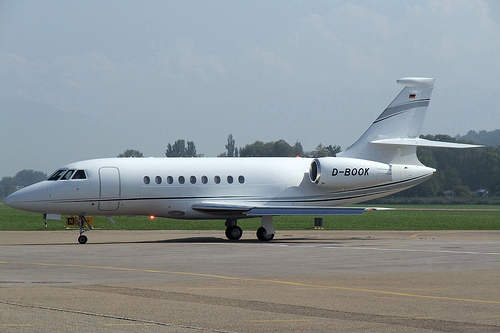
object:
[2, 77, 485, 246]
plane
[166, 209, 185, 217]
name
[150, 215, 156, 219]
light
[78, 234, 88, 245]
wheel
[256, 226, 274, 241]
wheel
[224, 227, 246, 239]
wheel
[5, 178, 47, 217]
nose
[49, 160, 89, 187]
cockpit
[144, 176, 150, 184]
window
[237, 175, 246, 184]
window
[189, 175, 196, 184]
window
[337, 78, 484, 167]
tail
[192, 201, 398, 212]
wing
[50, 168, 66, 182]
windshield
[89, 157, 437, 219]
body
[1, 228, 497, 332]
ground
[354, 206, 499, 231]
grass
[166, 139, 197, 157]
tree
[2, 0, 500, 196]
background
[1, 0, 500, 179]
sky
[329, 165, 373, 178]
letters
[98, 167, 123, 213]
door